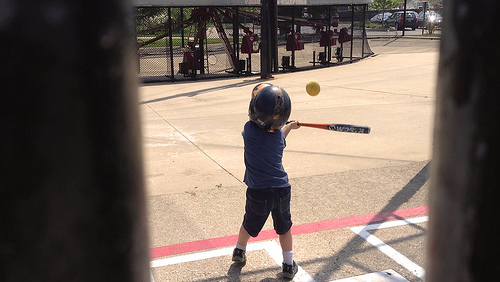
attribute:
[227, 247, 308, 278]
shoes — white, black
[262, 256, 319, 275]
shoes — black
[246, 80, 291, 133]
helmet — black, orange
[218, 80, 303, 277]
boy — little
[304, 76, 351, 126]
ball — yellow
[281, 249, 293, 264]
sock — white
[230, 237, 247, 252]
sock — white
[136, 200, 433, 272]
line — red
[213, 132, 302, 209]
shirt — navy blue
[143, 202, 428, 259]
line — red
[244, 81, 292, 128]
helmet — blue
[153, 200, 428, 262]
line — red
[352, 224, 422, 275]
line — white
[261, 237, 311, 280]
line — white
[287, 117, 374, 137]
bat — red, black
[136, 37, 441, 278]
concrete — light brown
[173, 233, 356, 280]
lines — white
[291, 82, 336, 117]
yellow baseball — large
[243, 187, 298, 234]
shorts — black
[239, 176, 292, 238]
shorts — jean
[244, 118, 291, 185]
shirt — blue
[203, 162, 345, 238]
shorts — dark blue, denim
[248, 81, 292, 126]
helmet — black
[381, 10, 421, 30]
vehicle — black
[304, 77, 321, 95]
ball — large, yellow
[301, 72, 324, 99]
ball — orange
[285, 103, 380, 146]
bat — black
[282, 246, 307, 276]
socks — white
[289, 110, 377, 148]
bat — red, black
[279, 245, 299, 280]
sock — white, black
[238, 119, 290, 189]
t-shirt — blue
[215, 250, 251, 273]
sock — white, black